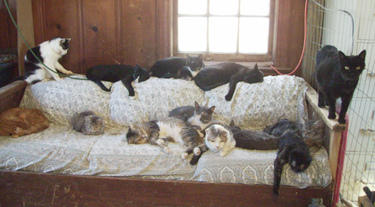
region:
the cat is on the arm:
[317, 93, 351, 135]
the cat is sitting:
[23, 67, 46, 87]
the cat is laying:
[101, 70, 145, 93]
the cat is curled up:
[11, 112, 40, 130]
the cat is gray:
[77, 115, 98, 131]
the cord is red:
[301, 20, 309, 40]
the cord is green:
[62, 68, 79, 85]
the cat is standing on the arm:
[315, 90, 350, 131]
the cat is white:
[45, 48, 55, 60]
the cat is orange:
[13, 110, 34, 125]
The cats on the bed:
[0, 34, 373, 193]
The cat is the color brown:
[3, 104, 51, 140]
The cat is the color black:
[306, 40, 367, 116]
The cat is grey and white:
[16, 26, 78, 93]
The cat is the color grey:
[222, 117, 283, 149]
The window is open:
[164, 4, 284, 67]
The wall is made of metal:
[344, 16, 374, 201]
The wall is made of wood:
[59, 9, 168, 51]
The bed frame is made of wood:
[31, 172, 193, 204]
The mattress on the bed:
[29, 138, 160, 173]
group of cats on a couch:
[0, 19, 360, 168]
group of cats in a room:
[13, 29, 367, 203]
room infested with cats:
[0, 35, 364, 183]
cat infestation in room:
[1, 30, 360, 177]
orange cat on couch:
[0, 98, 53, 136]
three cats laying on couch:
[115, 107, 239, 166]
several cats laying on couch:
[198, 105, 326, 187]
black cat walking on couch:
[308, 38, 373, 128]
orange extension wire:
[278, 9, 316, 57]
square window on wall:
[158, 0, 288, 61]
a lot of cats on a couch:
[0, 35, 365, 203]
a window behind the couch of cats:
[170, 0, 269, 60]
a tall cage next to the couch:
[300, 0, 370, 204]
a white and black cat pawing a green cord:
[11, 34, 71, 79]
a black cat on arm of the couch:
[311, 42, 362, 119]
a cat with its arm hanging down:
[263, 117, 310, 195]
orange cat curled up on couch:
[0, 105, 49, 135]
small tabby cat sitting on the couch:
[68, 107, 101, 132]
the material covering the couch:
[0, 71, 327, 182]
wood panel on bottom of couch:
[0, 168, 330, 203]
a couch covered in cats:
[2, 8, 351, 184]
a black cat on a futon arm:
[305, 29, 371, 115]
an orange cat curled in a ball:
[3, 106, 57, 155]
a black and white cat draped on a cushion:
[81, 56, 156, 101]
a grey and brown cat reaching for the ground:
[265, 119, 328, 196]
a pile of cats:
[132, 96, 235, 156]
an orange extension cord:
[290, 10, 319, 65]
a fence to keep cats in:
[353, 96, 373, 173]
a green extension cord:
[2, 4, 40, 60]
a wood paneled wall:
[78, 12, 151, 52]